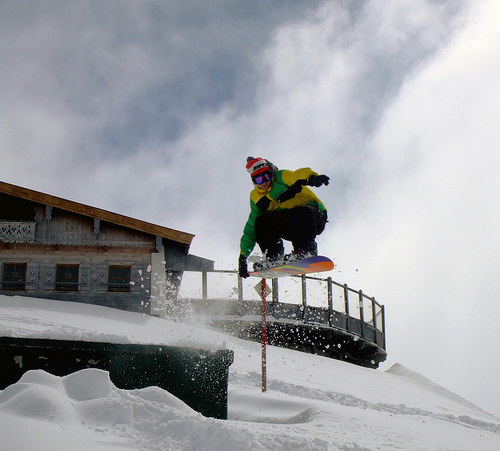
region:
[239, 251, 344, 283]
Person on a board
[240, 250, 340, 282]
Person is on a board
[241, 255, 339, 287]
Person on a snowboard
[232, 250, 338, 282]
Person is on a snowboard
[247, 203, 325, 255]
Person wearing pants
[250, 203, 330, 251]
Person is wearing pants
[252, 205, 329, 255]
Person wearing black pants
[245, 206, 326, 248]
Person is wearing black pants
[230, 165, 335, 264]
Person is wearing a jacket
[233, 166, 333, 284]
Person is wearing black gloves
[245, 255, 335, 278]
orange and blue snow board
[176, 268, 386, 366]
large patio on the side of a building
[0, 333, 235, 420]
rectangular ski and snow board jump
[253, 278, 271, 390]
sign standing out of snow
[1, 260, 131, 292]
three windows on a building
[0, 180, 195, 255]
wooden roof on a building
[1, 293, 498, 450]
deep white and fluffy snow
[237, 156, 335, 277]
Person on a snow board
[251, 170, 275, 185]
Large reflective safety ski goggles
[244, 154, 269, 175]
multi colored winter beanie hat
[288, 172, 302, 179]
the coat is yellow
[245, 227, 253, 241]
the coat is green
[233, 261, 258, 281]
he is holding the board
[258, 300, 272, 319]
the pole is red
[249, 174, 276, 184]
the person is wearing goggles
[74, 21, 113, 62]
the clouds are gray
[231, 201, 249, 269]
this is a man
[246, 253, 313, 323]
the board is plastic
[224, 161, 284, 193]
the goggles are purple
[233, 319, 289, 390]
the pole is red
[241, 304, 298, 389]
the pole is metal